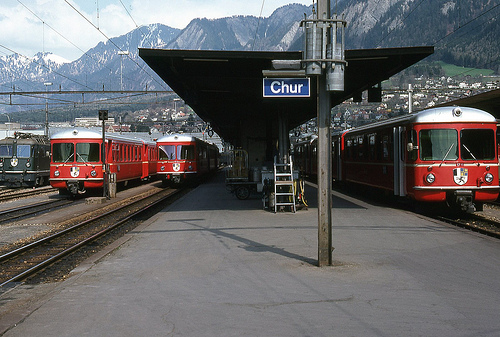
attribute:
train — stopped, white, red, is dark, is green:
[297, 104, 500, 231]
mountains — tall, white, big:
[12, 0, 490, 120]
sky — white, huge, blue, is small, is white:
[4, 1, 450, 75]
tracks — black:
[340, 162, 498, 242]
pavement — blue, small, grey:
[49, 139, 500, 335]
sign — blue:
[254, 62, 315, 132]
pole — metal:
[253, 50, 373, 291]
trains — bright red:
[44, 118, 484, 183]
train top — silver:
[58, 149, 132, 225]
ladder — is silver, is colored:
[274, 153, 296, 217]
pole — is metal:
[311, 3, 336, 270]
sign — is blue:
[262, 74, 312, 97]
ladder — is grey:
[272, 156, 297, 216]